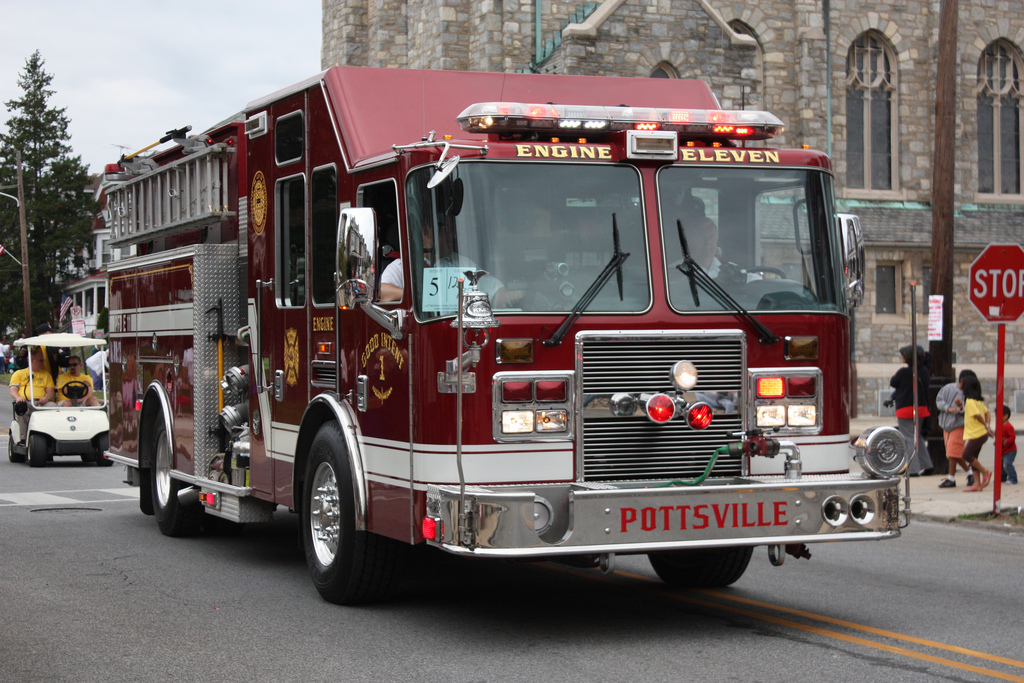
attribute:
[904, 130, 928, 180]
brick — in a wall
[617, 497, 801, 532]
pottsville — written in red letters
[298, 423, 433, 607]
tire —  vehicle's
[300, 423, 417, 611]
tire —  vehicle's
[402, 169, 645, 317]
window —  vehicle's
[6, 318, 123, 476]
golf cart — small, white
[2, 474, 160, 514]
crosswalk — pedestrian, marked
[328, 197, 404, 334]
sideview mirror — chrome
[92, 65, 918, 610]
fire truck — red, moving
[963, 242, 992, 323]
stop sign — red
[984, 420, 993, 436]
hand — little brothers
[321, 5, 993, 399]
building — a church, large, stone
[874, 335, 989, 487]
people — a group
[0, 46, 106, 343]
tree — pine, tall, green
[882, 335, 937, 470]
person — standing up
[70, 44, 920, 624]
fire engine — red